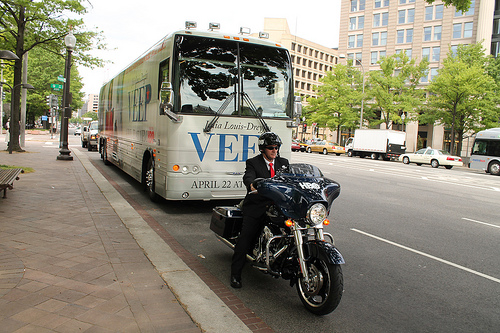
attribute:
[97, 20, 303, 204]
bus — white, blue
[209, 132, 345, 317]
motorcycle — black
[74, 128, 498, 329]
street — black, asphalt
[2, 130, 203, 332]
sidewalk — paved, tiled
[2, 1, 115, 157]
tree — green, large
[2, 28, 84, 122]
tree — green, large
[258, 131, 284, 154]
helmet — black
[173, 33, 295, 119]
windshield — glass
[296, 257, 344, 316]
tire — black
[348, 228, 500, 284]
line — white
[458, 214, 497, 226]
line — white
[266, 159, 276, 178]
tie — red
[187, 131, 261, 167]
letters — blue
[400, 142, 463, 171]
cab — parked